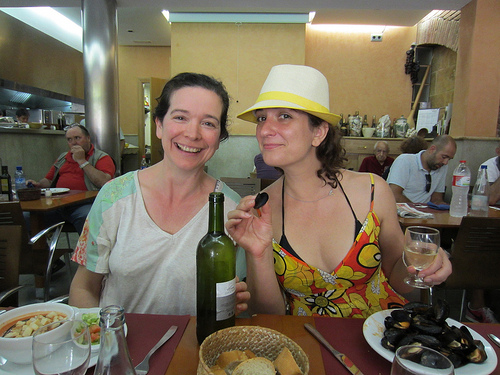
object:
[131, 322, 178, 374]
silver fork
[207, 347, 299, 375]
bread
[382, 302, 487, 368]
mussels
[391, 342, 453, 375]
clear glass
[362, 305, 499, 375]
white plate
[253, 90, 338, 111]
stripe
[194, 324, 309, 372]
basket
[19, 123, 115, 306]
man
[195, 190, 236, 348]
bottle table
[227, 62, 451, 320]
woman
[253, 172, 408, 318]
dress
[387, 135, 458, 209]
man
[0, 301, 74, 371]
bowl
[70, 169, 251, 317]
shirt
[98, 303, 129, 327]
top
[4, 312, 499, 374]
table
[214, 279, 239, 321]
label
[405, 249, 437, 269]
wine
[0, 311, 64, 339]
soup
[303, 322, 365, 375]
knife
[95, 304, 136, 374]
bottle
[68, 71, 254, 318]
woman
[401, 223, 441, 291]
glass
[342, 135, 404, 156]
shelf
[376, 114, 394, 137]
item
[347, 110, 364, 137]
item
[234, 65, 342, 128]
hat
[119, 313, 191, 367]
placemat